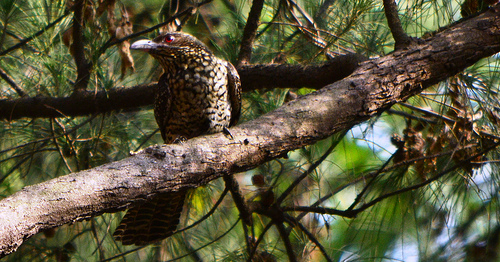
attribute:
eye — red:
[161, 31, 182, 45]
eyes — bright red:
[160, 29, 179, 42]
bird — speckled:
[102, 27, 249, 251]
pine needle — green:
[405, 170, 422, 260]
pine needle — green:
[352, 137, 394, 156]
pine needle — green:
[486, 147, 494, 248]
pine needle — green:
[347, 255, 403, 260]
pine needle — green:
[432, 0, 440, 30]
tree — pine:
[5, 1, 494, 251]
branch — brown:
[2, 0, 497, 259]